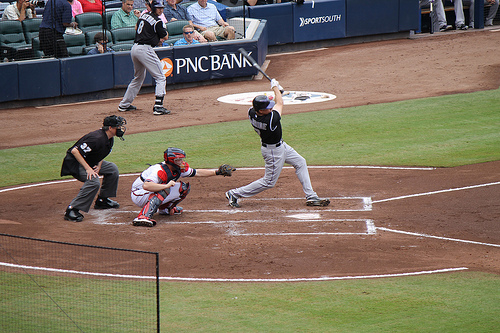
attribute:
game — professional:
[8, 66, 488, 333]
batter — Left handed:
[218, 43, 339, 212]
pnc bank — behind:
[173, 45, 263, 75]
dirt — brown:
[0, 26, 500, 286]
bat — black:
[236, 41, 291, 95]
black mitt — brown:
[214, 160, 242, 180]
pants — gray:
[231, 142, 323, 199]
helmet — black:
[248, 92, 276, 117]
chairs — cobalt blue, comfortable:
[4, 15, 132, 54]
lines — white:
[209, 170, 383, 238]